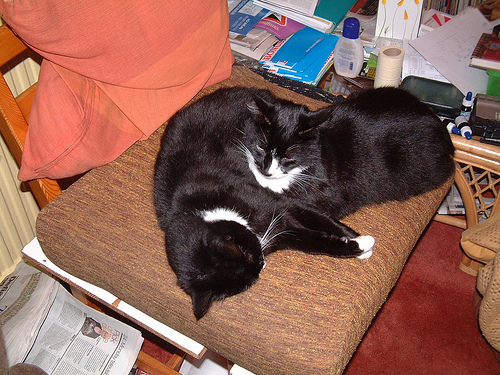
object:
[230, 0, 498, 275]
table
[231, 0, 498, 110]
clutter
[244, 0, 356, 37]
papers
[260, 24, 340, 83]
envelopes